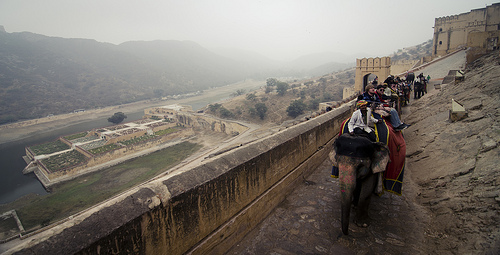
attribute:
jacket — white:
[347, 108, 378, 135]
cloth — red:
[373, 114, 418, 199]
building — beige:
[430, 0, 496, 60]